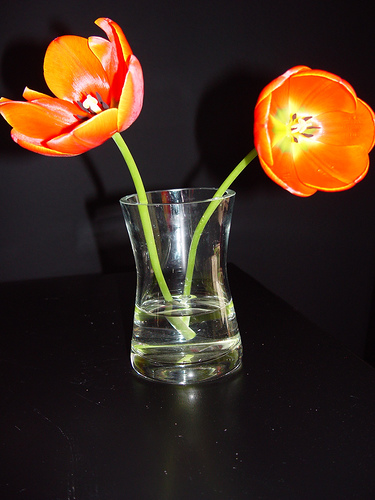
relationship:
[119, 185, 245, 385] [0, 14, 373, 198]
vase of tulips